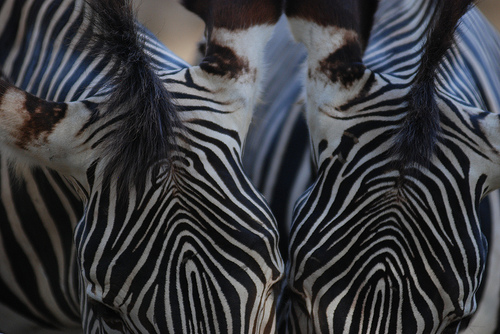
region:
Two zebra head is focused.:
[31, 49, 472, 308]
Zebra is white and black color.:
[47, 166, 446, 256]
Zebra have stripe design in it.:
[11, 164, 444, 294]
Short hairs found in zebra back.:
[103, 24, 448, 188]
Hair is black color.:
[87, 31, 197, 179]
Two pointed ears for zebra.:
[12, 43, 293, 175]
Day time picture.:
[12, 28, 489, 322]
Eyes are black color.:
[63, 278, 132, 332]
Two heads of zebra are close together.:
[26, 55, 474, 331]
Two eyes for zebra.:
[76, 257, 298, 329]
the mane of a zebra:
[70, 5, 210, 192]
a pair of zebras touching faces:
[3, 13, 493, 323]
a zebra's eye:
[71, 285, 148, 328]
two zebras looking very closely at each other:
[247, 244, 331, 322]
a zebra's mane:
[385, 1, 486, 196]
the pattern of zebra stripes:
[102, 173, 244, 331]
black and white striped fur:
[342, 184, 430, 305]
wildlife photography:
[0, 5, 462, 326]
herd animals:
[35, 15, 497, 330]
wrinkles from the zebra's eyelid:
[66, 279, 167, 321]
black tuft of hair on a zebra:
[108, 72, 188, 178]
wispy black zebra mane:
[389, 74, 456, 199]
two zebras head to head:
[42, 88, 476, 333]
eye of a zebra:
[76, 280, 133, 327]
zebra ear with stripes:
[3, 73, 107, 179]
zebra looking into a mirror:
[69, 14, 422, 303]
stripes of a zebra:
[102, 196, 214, 270]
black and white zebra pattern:
[10, 191, 57, 263]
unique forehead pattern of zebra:
[153, 224, 224, 316]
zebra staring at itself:
[94, 136, 436, 331]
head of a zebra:
[168, 187, 220, 260]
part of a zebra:
[367, 227, 405, 291]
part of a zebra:
[163, 230, 222, 306]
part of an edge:
[241, 6, 256, 30]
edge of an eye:
[87, 285, 130, 325]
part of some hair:
[128, 55, 187, 145]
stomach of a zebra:
[253, 101, 297, 167]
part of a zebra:
[202, 208, 236, 270]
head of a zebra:
[366, 203, 402, 278]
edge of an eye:
[82, 263, 135, 320]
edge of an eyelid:
[238, 260, 289, 300]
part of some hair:
[121, 140, 156, 185]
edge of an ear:
[67, 150, 109, 191]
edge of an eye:
[276, 258, 316, 317]